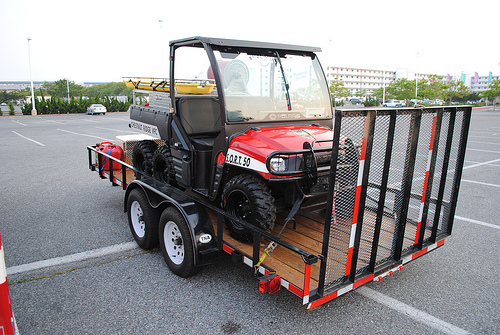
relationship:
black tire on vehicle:
[218, 172, 278, 244] [128, 35, 361, 242]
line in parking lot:
[10, 129, 45, 149] [7, 109, 482, 326]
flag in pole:
[486, 69, 494, 93] [456, 72, 470, 91]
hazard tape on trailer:
[94, 166, 128, 188] [87, 104, 472, 310]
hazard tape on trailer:
[222, 245, 300, 299] [87, 104, 472, 310]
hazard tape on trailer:
[302, 263, 310, 304] [87, 104, 472, 310]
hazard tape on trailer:
[344, 117, 369, 275] [87, 104, 472, 310]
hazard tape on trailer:
[414, 112, 438, 244] [87, 104, 472, 310]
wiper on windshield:
[270, 48, 295, 110] [206, 35, 339, 124]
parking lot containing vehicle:
[7, 109, 482, 326] [86, 100, 110, 118]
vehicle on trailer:
[113, 23, 375, 258] [95, 74, 468, 312]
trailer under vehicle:
[87, 104, 472, 310] [128, 35, 361, 242]